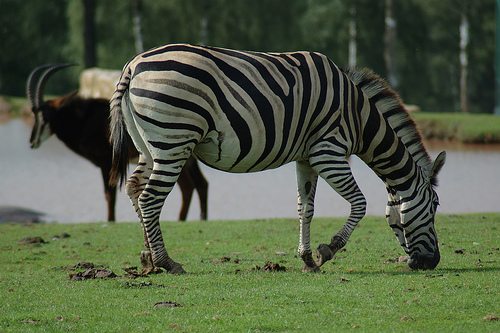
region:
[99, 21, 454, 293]
zebra is in the grass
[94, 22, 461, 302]
zebra is a four legged mammal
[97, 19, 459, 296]
zebra has many black stripes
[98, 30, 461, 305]
zebra is eating on some green grass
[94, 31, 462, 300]
zebra is white and has many stripes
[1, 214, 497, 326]
the grass is green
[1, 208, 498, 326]
grass is neatly trimmed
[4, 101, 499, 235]
water is brown and dirty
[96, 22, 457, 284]
zebra is grazing in the wild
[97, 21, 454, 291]
zebra has some faded black stripes that look gray.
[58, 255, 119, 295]
clump of brown dirt on ground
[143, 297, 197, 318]
small indent in the grass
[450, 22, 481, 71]
white spot on tree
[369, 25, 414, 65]
wide gray base on tree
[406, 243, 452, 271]
zebra eating green grass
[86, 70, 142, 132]
small tail on zebra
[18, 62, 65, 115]
pointed black horns on animal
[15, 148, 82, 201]
blue body of water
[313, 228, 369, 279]
zebra's upraised foot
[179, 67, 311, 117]
black and white stripes on zebra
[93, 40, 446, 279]
zebra on the grass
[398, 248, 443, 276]
zebra is eating grass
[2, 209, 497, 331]
grass is very green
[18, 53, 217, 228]
ram is behind zebra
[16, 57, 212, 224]
ram is dark brown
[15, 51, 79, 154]
ram has two horns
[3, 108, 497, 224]
animals are in front of lake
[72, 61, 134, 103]
rock is on the other side of lake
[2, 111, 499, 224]
lake is full of water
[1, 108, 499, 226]
water is muddy brown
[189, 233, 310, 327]
the grass is green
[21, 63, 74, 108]
the horns are curved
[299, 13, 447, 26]
the trees are green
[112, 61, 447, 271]
the zebra is eating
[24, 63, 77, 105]
the horns are black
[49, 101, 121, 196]
the animal is brown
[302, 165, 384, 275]
one leg is bent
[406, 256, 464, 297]
the mouth is black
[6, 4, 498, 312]
photo was taken during the day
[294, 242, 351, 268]
the hoves are grey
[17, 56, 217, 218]
sable antelope, blurry behind zebra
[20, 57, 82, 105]
curved dark horns of sable antelope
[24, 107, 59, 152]
black+white striped face of sable antelope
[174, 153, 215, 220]
backwards-bent knees of sable antelope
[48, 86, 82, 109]
pointy rusty brown ear of sable antelope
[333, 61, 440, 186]
dusty striped zebra main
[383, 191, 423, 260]
indentation of zebra's lower jaw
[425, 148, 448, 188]
mane fur before+behind zebra ear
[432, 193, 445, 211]
zebra's long dark eyelash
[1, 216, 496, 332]
i hope it's mud